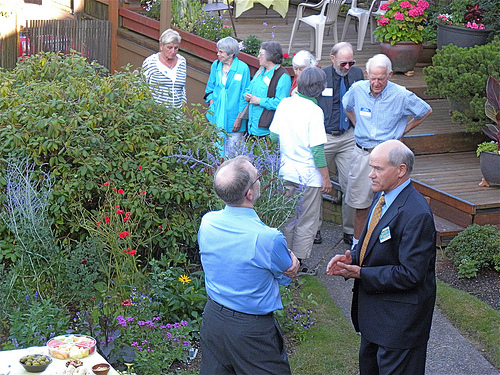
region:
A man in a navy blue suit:
[328, 135, 445, 371]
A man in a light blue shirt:
[185, 148, 301, 374]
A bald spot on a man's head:
[210, 157, 242, 190]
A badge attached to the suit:
[377, 222, 394, 246]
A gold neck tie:
[351, 192, 391, 271]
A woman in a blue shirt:
[197, 31, 257, 137]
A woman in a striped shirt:
[134, 28, 191, 114]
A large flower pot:
[375, 36, 427, 76]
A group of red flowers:
[86, 162, 148, 294]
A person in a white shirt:
[256, 62, 334, 276]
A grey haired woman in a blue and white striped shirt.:
[141, 26, 188, 111]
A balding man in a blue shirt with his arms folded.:
[196, 155, 301, 373]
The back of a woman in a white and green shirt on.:
[268, 68, 331, 273]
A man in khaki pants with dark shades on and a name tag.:
[316, 42, 365, 246]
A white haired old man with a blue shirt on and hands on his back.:
[340, 52, 433, 249]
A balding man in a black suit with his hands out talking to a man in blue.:
[325, 138, 433, 374]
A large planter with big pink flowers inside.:
[376, 1, 428, 73]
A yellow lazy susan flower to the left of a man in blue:
[178, 272, 191, 285]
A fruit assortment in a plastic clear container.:
[45, 332, 95, 359]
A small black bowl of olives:
[18, 353, 52, 373]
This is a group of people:
[141, 100, 393, 354]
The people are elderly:
[100, 79, 406, 324]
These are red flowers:
[101, 198, 156, 282]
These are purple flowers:
[112, 297, 189, 372]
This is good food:
[35, 306, 105, 371]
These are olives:
[2, 350, 57, 362]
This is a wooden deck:
[442, 160, 490, 227]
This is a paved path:
[333, 285, 358, 366]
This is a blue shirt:
[201, 95, 232, 121]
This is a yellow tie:
[357, 205, 391, 228]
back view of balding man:
[195, 153, 292, 368]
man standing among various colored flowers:
[36, 155, 302, 281]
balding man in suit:
[358, 146, 430, 356]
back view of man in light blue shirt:
[190, 164, 297, 338]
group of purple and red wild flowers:
[99, 158, 181, 350]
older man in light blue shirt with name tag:
[351, 55, 402, 145]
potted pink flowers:
[385, 9, 435, 54]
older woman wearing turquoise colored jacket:
[203, 40, 247, 128]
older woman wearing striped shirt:
[145, 23, 192, 105]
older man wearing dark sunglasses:
[327, 45, 359, 79]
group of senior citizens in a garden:
[65, 6, 465, 365]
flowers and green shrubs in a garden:
[0, 69, 197, 334]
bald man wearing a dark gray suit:
[313, 139, 450, 355]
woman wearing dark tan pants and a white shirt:
[247, 65, 334, 273]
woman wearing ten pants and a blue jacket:
[196, 32, 257, 160]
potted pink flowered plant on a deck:
[357, 0, 447, 87]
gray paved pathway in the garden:
[275, 214, 489, 361]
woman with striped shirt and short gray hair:
[127, 23, 197, 135]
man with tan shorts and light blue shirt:
[313, 45, 439, 221]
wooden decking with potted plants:
[414, 110, 495, 237]